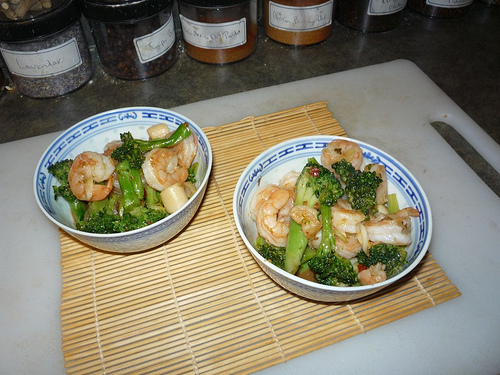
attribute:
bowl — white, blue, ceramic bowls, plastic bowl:
[232, 135, 432, 304]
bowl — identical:
[32, 106, 211, 255]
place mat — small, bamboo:
[62, 247, 246, 374]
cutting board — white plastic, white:
[344, 59, 489, 137]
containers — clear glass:
[1, 0, 94, 99]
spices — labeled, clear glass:
[83, 2, 178, 80]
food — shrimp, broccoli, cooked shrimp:
[259, 140, 416, 282]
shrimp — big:
[69, 150, 116, 203]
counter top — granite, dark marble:
[341, 19, 499, 57]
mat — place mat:
[61, 255, 251, 375]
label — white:
[1, 39, 82, 79]